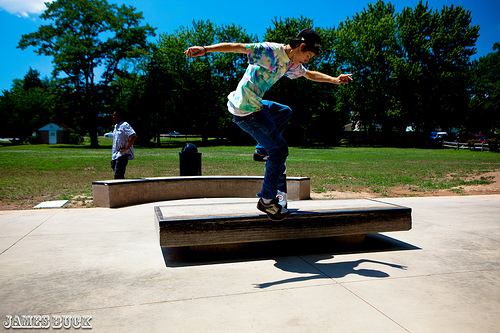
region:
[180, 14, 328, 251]
PErson on a skate board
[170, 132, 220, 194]
Medium size trash can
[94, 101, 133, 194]
Man walking on the grass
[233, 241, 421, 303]
Black shadow on the pavement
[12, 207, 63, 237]
Large cracks in the pavement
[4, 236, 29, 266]
Large cracks in the pavement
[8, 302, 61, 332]
Large cracks in the pavement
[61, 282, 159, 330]
Large cracks in the pavement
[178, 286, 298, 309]
Large cracks in the pavement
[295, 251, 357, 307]
Large cracks in the pavement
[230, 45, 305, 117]
boy's shirt has many colors on it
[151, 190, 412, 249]
concrete skateboarding structure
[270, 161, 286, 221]
skateboard under the boy's feet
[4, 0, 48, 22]
single cloud in the sky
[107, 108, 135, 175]
man standing behind the concrete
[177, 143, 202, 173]
public trash can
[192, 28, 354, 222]
young man doing a skateboard trick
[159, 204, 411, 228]
metal edging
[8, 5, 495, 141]
tall trees along the edge of the park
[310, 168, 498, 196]
dirt patches along the grass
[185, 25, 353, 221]
A man in a tye dye shirt and jeans skating.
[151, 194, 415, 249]
A long concrete bench.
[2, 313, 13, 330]
A white and grey J in JAMES.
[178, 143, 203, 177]
A black trashcan.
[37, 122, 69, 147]
A red and white building through the field.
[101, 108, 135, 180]
A person with black hair and dark skin walking in a white shirt.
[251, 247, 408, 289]
Shadow of a skateboarder.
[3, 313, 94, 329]
The name JAMES BUCK.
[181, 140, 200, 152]
The black top of a trashcan.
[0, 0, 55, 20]
A white cloud in the blue sky.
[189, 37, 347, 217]
boy wearing black shoes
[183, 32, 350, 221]
boy wearing long pants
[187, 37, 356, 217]
boy wearing blue pants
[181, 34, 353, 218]
boy wearing short sleeves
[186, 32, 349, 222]
boy wearing colorful shirt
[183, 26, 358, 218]
boy wearing backwards hat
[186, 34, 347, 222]
boy wearing blue hat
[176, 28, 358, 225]
boy jumping on skateboard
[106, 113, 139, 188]
man wearing blue pants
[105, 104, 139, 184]
man wearing long pants